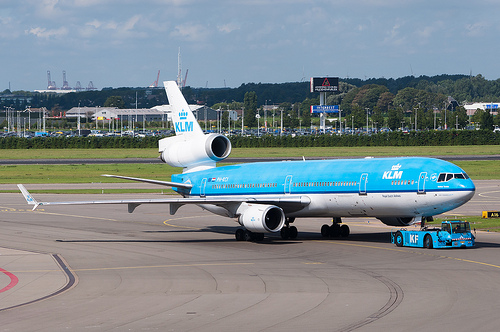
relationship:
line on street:
[446, 254, 496, 271] [40, 263, 412, 311]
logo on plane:
[381, 168, 403, 180] [17, 79, 474, 243]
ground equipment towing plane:
[388, 218, 480, 251] [13, 82, 477, 224]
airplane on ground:
[14, 77, 476, 242] [44, 240, 384, 315]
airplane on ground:
[15, 77, 476, 242] [273, 246, 396, 287]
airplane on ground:
[14, 77, 476, 242] [0, 194, 495, 330]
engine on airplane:
[236, 197, 288, 235] [15, 77, 476, 242]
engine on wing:
[236, 197, 288, 235] [14, 180, 311, 211]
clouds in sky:
[9, 21, 486, 57] [1, 7, 489, 102]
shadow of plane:
[53, 222, 397, 248] [17, 79, 474, 243]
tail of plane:
[153, 85, 220, 197] [18, 70, 486, 248]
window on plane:
[320, 182, 324, 188] [17, 79, 474, 243]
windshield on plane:
[438, 170, 469, 182] [17, 79, 474, 243]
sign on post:
[310, 72, 351, 94] [314, 84, 329, 131]